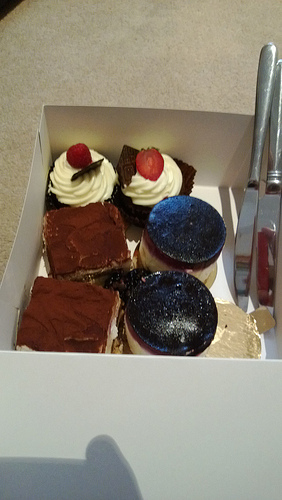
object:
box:
[0, 104, 281, 497]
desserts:
[122, 268, 218, 357]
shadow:
[0, 434, 141, 500]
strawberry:
[134, 147, 165, 182]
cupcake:
[115, 142, 197, 229]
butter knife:
[255, 59, 281, 317]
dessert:
[137, 194, 226, 284]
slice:
[14, 274, 122, 356]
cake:
[41, 200, 133, 286]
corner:
[42, 106, 56, 168]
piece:
[41, 202, 135, 286]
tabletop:
[0, 0, 280, 285]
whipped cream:
[119, 152, 183, 209]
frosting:
[42, 199, 132, 278]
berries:
[103, 266, 153, 310]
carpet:
[0, 0, 282, 287]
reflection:
[255, 219, 276, 308]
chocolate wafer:
[115, 143, 139, 190]